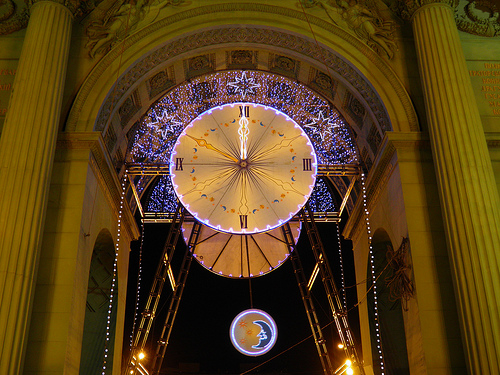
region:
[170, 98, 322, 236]
round golden clockface suspended from arch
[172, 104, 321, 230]
golden clock face with four Roman numerals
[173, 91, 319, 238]
time reads 5:50 on golden clock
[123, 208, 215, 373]
silver scaffolding leading to clock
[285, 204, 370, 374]
silver scaffolding leading to clock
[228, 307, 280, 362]
round sun and moon motif hanging below clock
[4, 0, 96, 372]
large stone pillar on side of clock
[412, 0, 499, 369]
large stone pillar bordering building arch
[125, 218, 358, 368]
black evening sky outdoors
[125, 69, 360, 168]
arch of lighted star display in white and blue above clock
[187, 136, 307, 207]
A clock in the photo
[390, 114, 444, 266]
Pillars in the building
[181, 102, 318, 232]
Illuminated lights on the clock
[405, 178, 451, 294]
Stone wall in the photo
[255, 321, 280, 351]
Crescent in the photo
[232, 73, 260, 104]
Star on the clock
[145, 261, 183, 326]
Metal bars on the building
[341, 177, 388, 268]
Lights on the building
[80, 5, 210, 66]
Engraved statue on the wall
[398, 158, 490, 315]
A building in the photo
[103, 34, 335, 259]
this is a clock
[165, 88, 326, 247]
tan face of clock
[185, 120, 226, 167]
golden hand on clock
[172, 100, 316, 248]
clock face is lit up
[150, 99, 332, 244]
white light around clock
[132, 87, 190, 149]
this is a star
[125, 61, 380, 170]
three stars around clock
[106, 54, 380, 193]
the stars are illuminated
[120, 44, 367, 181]
the stars are light purple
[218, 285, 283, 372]
lit moon in background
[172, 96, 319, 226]
a colorful clock face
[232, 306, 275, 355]
a festive clock bell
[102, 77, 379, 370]
a very festive clock tower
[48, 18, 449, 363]
a clock tower under an archway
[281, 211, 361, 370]
two support beams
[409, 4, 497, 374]
a tall elegant pillar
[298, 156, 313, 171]
the roman numeral 3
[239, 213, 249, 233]
the roman numeral 6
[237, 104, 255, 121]
roman numeral 12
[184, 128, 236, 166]
the minute hand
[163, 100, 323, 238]
ORNATE CLOCK IN BUILDING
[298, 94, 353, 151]
ORNATE DECORATION ABOVE CLOCK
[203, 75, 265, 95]
ORNATE DECORATION ABOVE CLOCK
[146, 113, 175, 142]
ORNATE DECORATION ABOVE CLOCK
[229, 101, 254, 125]
ROMAN NUMBER 12 ON CLOCK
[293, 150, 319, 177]
ROMAN NUMBER 3 ON CLOCK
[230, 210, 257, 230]
NUMBER 6 ON CLOCK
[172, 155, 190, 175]
NUMBER 9 ON CLOCK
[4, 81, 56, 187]
TALL GOLDEN BUILDING COLUMN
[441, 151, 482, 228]
TALL GOLDEN BUILDING COLUMN